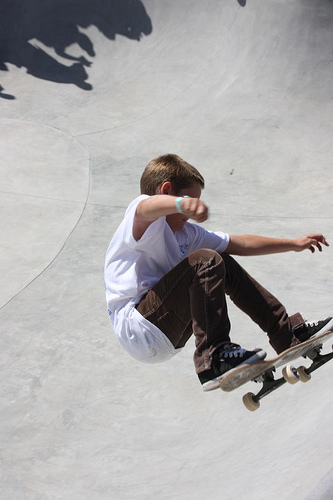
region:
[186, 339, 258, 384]
Black and white shoe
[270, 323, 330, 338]
Black and white shoe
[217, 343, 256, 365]
White laces on black shoe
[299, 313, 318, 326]
White laces on black shoe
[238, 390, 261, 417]
White wheel on a skateboard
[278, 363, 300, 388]
White wheel on a skateboard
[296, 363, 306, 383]
White wheel on a skateboard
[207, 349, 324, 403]
Black and white skateboard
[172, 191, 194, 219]
White bracelet on a wrist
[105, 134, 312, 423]
Small child riding a skateboard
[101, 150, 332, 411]
A young boy is riding a skateboard.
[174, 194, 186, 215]
The boy is wearing a light blue wristband.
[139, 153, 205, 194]
The boy has short, brown hair.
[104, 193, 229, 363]
The boy is wearing a white T-shirt.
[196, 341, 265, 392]
The skater shoes are black and white.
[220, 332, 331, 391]
The skateboard is brown.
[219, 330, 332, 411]
The skateboard is flying in the air.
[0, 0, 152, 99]
The shadows of other people.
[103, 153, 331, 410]
The boy is doing a trick on his skateboard.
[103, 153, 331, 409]
The boy is jumping in the air.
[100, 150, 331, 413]
Boy skating on skate ramp.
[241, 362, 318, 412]
White wheels on the skateboard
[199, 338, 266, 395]
Black shoe on the foot.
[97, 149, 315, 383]
Brown pants on the boy.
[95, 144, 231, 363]
White t-shirt on the boy.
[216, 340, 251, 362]
White shoelaces on shoes.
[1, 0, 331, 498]
cement covering the ground.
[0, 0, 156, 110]
Shadow on the pavement.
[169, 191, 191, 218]
Blue band on the wrist.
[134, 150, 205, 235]
Brown hair on the boy.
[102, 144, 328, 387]
this is a boy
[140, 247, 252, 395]
the leg of a boy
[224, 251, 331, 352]
the leg of a boy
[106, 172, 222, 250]
the hand of a boy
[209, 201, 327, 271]
the hand of a boy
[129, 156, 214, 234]
the head of a boy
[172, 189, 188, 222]
this is a wrist watch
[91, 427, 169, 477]
the ground is gray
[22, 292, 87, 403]
the ground is gray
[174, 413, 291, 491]
the ground is gray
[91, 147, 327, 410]
A boy skateboarding in a skate bowl